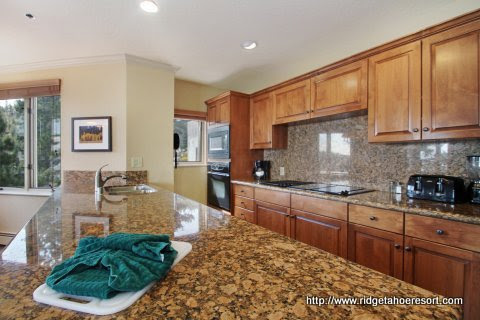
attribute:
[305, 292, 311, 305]
letter — white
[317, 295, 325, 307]
letter — white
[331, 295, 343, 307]
letter — white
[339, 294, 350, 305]
letter — white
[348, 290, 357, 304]
letter — white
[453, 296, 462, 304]
letter — white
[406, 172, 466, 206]
toaster — black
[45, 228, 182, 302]
towel — green, dish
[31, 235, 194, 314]
cutting board — white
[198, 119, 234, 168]
microwave — black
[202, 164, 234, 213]
oven — black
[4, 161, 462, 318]
table top — granite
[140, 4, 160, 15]
light — recessed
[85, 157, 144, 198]
faucet — silver, metal, sink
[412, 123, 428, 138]
knobs — metal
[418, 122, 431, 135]
knobs — metal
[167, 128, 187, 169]
phone — black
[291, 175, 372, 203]
stove top — black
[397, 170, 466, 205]
toaster — black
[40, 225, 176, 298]
towel — green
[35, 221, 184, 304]
towel — green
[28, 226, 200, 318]
board — cutting, white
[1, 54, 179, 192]
wall — light brown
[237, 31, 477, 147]
cabinets — brown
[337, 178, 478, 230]
counter — brown, black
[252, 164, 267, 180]
pot — coffee, black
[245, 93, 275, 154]
door — wood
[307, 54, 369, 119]
door — wood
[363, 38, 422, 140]
door — wood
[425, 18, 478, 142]
door — wood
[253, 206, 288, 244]
door — wood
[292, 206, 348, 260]
door — wood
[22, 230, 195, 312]
cutting board — white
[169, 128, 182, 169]
phone — black, corded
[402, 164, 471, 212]
toaster — black, double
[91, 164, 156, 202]
sink — kitchen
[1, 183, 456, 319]
countertops — brown, marble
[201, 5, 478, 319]
cabinets — brown, wooden, kitchen